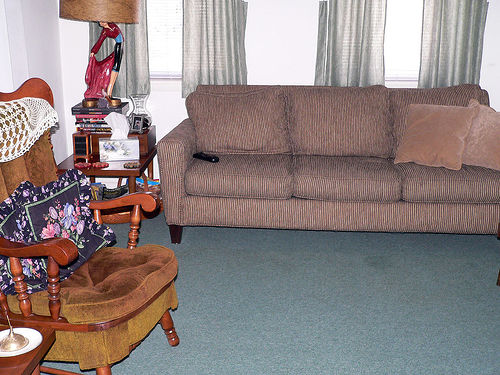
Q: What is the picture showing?
A: It is showing a living room.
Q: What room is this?
A: It is a living room.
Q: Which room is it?
A: It is a living room.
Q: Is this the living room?
A: Yes, it is the living room.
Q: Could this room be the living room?
A: Yes, it is the living room.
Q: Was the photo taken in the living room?
A: Yes, it was taken in the living room.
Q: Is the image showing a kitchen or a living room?
A: It is showing a living room.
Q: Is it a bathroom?
A: No, it is a living room.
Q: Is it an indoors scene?
A: Yes, it is indoors.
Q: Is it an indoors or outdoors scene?
A: It is indoors.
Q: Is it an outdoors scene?
A: No, it is indoors.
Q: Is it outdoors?
A: No, it is indoors.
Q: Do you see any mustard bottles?
A: No, there are no mustard bottles.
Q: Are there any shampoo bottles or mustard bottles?
A: No, there are no mustard bottles or shampoo bottles.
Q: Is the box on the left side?
A: Yes, the box is on the left of the image.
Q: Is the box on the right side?
A: No, the box is on the left of the image.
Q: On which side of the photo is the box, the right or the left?
A: The box is on the left of the image.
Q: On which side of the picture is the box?
A: The box is on the left of the image.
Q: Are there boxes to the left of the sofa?
A: Yes, there is a box to the left of the sofa.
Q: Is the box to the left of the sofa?
A: Yes, the box is to the left of the sofa.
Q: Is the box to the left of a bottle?
A: No, the box is to the left of the sofa.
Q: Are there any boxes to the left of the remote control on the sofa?
A: Yes, there is a box to the left of the remote.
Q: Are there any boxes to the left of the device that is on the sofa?
A: Yes, there is a box to the left of the remote.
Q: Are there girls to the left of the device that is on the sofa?
A: No, there is a box to the left of the remote.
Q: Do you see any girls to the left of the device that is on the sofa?
A: No, there is a box to the left of the remote.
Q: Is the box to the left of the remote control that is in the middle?
A: Yes, the box is to the left of the remote.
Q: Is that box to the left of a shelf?
A: No, the box is to the left of the remote.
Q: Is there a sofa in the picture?
A: Yes, there is a sofa.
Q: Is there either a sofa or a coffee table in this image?
A: Yes, there is a sofa.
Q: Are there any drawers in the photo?
A: No, there are no drawers.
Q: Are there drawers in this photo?
A: No, there are no drawers.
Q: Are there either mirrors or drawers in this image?
A: No, there are no drawers or mirrors.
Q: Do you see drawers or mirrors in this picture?
A: No, there are no drawers or mirrors.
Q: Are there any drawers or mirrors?
A: No, there are no drawers or mirrors.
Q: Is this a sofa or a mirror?
A: This is a sofa.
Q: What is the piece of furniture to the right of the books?
A: The piece of furniture is a sofa.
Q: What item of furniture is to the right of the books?
A: The piece of furniture is a sofa.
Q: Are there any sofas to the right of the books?
A: Yes, there is a sofa to the right of the books.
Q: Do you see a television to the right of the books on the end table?
A: No, there is a sofa to the right of the books.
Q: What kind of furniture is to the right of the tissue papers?
A: The piece of furniture is a sofa.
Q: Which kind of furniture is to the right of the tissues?
A: The piece of furniture is a sofa.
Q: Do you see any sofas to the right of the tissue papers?
A: Yes, there is a sofa to the right of the tissue papers.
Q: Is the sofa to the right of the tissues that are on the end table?
A: Yes, the sofa is to the right of the tissue papers.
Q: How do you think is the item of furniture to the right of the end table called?
A: The piece of furniture is a sofa.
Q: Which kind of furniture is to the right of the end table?
A: The piece of furniture is a sofa.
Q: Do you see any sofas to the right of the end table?
A: Yes, there is a sofa to the right of the end table.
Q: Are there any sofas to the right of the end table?
A: Yes, there is a sofa to the right of the end table.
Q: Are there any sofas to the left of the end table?
A: No, the sofa is to the right of the end table.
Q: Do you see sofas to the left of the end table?
A: No, the sofa is to the right of the end table.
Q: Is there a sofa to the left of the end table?
A: No, the sofa is to the right of the end table.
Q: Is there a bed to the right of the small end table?
A: No, there is a sofa to the right of the end table.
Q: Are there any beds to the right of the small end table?
A: No, there is a sofa to the right of the end table.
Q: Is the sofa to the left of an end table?
A: No, the sofa is to the right of an end table.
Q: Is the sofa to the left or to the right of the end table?
A: The sofa is to the right of the end table.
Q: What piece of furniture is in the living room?
A: The piece of furniture is a sofa.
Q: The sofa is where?
A: The sofa is in the living room.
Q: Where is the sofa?
A: The sofa is in the living room.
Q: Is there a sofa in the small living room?
A: Yes, there is a sofa in the living room.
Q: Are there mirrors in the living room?
A: No, there is a sofa in the living room.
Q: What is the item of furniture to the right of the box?
A: The piece of furniture is a sofa.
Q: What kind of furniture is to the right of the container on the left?
A: The piece of furniture is a sofa.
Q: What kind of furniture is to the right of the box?
A: The piece of furniture is a sofa.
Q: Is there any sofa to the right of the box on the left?
A: Yes, there is a sofa to the right of the box.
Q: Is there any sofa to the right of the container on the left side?
A: Yes, there is a sofa to the right of the box.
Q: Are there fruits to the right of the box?
A: No, there is a sofa to the right of the box.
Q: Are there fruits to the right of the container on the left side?
A: No, there is a sofa to the right of the box.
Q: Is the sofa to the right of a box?
A: Yes, the sofa is to the right of a box.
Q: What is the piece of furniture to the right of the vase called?
A: The piece of furniture is a sofa.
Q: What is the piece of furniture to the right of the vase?
A: The piece of furniture is a sofa.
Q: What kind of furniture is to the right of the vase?
A: The piece of furniture is a sofa.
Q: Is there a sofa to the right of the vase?
A: Yes, there is a sofa to the right of the vase.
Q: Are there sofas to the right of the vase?
A: Yes, there is a sofa to the right of the vase.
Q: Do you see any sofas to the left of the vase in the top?
A: No, the sofa is to the right of the vase.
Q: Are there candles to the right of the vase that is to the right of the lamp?
A: No, there is a sofa to the right of the vase.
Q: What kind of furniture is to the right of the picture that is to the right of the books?
A: The piece of furniture is a sofa.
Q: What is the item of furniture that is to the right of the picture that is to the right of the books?
A: The piece of furniture is a sofa.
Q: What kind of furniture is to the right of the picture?
A: The piece of furniture is a sofa.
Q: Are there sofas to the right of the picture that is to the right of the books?
A: Yes, there is a sofa to the right of the picture.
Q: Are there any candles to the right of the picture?
A: No, there is a sofa to the right of the picture.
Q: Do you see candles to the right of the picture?
A: No, there is a sofa to the right of the picture.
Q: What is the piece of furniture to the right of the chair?
A: The piece of furniture is a sofa.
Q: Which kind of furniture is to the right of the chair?
A: The piece of furniture is a sofa.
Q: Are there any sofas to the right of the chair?
A: Yes, there is a sofa to the right of the chair.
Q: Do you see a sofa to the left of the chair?
A: No, the sofa is to the right of the chair.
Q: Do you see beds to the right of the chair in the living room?
A: No, there is a sofa to the right of the chair.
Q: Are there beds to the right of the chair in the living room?
A: No, there is a sofa to the right of the chair.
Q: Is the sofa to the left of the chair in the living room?
A: No, the sofa is to the right of the chair.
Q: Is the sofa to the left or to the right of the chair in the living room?
A: The sofa is to the right of the chair.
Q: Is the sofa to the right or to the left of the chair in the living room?
A: The sofa is to the right of the chair.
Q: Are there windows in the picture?
A: Yes, there are windows.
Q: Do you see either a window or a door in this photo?
A: Yes, there are windows.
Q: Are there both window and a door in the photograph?
A: No, there are windows but no doors.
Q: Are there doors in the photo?
A: No, there are no doors.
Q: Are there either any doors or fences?
A: No, there are no doors or fences.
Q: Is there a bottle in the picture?
A: No, there are no bottles.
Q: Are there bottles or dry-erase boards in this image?
A: No, there are no bottles or dry-erase boards.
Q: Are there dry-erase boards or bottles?
A: No, there are no bottles or dry-erase boards.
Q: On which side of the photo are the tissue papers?
A: The tissue papers are on the left of the image.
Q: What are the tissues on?
A: The tissues are on the end table.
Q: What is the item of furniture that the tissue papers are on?
A: The piece of furniture is an end table.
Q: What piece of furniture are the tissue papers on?
A: The tissue papers are on the end table.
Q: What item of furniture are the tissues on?
A: The tissue papers are on the end table.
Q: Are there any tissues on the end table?
A: Yes, there are tissues on the end table.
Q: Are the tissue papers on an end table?
A: Yes, the tissue papers are on an end table.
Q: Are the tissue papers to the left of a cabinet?
A: No, the tissue papers are to the left of a sofa.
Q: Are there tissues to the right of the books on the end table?
A: Yes, there are tissues to the right of the books.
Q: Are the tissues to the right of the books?
A: Yes, the tissues are to the right of the books.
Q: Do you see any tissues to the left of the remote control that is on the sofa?
A: Yes, there are tissues to the left of the remote.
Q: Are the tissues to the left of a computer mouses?
A: No, the tissues are to the left of the remote control.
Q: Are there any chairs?
A: Yes, there is a chair.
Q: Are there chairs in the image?
A: Yes, there is a chair.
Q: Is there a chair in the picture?
A: Yes, there is a chair.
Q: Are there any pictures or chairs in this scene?
A: Yes, there is a chair.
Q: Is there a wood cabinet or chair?
A: Yes, there is a wood chair.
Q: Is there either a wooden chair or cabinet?
A: Yes, there is a wood chair.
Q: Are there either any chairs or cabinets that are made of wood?
A: Yes, the chair is made of wood.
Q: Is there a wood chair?
A: Yes, there is a chair that is made of wood.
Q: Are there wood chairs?
A: Yes, there is a chair that is made of wood.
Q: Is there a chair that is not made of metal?
A: Yes, there is a chair that is made of wood.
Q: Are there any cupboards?
A: No, there are no cupboards.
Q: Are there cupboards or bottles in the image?
A: No, there are no cupboards or bottles.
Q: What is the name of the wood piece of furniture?
A: The piece of furniture is a chair.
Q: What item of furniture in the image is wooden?
A: The piece of furniture is a chair.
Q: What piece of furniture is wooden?
A: The piece of furniture is a chair.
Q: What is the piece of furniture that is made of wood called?
A: The piece of furniture is a chair.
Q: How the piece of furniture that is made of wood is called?
A: The piece of furniture is a chair.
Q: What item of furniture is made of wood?
A: The piece of furniture is a chair.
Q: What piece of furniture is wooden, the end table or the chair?
A: The chair is wooden.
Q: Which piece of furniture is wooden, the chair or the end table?
A: The chair is wooden.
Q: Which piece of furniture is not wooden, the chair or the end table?
A: The end table is not wooden.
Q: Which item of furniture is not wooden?
A: The piece of furniture is an end table.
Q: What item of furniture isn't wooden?
A: The piece of furniture is an end table.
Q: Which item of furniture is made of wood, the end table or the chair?
A: The chair is made of wood.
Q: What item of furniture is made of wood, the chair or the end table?
A: The chair is made of wood.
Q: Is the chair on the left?
A: Yes, the chair is on the left of the image.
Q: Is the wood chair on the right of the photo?
A: No, the chair is on the left of the image.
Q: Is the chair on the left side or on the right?
A: The chair is on the left of the image.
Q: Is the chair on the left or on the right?
A: The chair is on the left of the image.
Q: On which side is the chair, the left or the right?
A: The chair is on the left of the image.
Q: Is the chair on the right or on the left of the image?
A: The chair is on the left of the image.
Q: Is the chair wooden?
A: Yes, the chair is wooden.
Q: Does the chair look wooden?
A: Yes, the chair is wooden.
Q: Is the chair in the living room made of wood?
A: Yes, the chair is made of wood.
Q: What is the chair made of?
A: The chair is made of wood.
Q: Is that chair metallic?
A: No, the chair is wooden.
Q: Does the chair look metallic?
A: No, the chair is wooden.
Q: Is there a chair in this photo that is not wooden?
A: No, there is a chair but it is wooden.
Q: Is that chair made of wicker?
A: No, the chair is made of wood.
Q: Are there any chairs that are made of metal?
A: No, there is a chair but it is made of wood.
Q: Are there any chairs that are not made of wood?
A: No, there is a chair but it is made of wood.